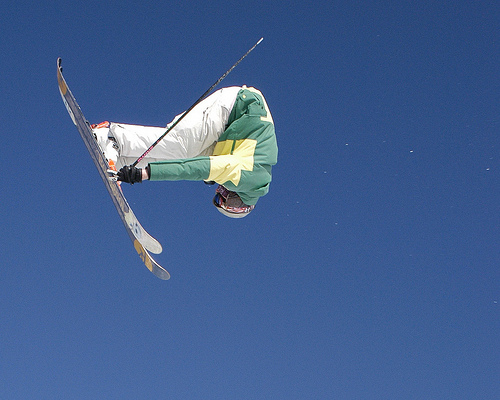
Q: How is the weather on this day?
A: It is clear.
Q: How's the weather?
A: It is clear.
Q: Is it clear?
A: Yes, it is clear.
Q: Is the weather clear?
A: Yes, it is clear.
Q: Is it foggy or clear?
A: It is clear.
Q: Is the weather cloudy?
A: No, it is clear.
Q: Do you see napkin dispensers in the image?
A: No, there are no napkin dispensers.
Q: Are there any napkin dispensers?
A: No, there are no napkin dispensers.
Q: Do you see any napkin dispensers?
A: No, there are no napkin dispensers.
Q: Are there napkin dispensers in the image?
A: No, there are no napkin dispensers.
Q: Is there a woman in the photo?
A: No, there are no women.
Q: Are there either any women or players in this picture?
A: No, there are no women or players.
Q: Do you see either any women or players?
A: No, there are no women or players.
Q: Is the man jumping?
A: Yes, the man is jumping.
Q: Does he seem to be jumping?
A: Yes, the man is jumping.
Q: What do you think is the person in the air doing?
A: The man is jumping.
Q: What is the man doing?
A: The man is jumping.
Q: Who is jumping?
A: The man is jumping.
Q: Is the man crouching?
A: No, the man is jumping.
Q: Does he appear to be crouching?
A: No, the man is jumping.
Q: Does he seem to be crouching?
A: No, the man is jumping.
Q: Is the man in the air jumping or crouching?
A: The man is jumping.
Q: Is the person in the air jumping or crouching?
A: The man is jumping.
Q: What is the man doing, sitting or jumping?
A: The man is jumping.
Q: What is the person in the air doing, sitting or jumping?
A: The man is jumping.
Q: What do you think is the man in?
A: The man is in the air.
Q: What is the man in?
A: The man is in the air.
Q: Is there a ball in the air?
A: No, there is a man in the air.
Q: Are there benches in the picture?
A: No, there are no benches.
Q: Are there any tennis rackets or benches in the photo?
A: No, there are no benches or tennis rackets.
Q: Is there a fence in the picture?
A: No, there are no fences.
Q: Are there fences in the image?
A: No, there are no fences.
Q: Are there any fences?
A: No, there are no fences.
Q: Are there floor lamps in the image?
A: No, there are no floor lamps.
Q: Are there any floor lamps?
A: No, there are no floor lamps.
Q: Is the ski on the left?
A: Yes, the ski is on the left of the image.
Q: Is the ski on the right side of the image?
A: No, the ski is on the left of the image.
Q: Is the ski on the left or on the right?
A: The ski is on the left of the image.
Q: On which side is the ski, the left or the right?
A: The ski is on the left of the image.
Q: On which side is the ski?
A: The ski is on the left of the image.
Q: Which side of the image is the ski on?
A: The ski is on the left of the image.